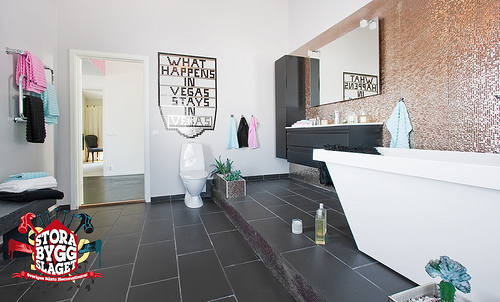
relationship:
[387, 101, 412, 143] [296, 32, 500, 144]
towel on wall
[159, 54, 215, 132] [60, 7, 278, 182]
poster on wall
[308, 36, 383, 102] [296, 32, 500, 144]
mirror on wall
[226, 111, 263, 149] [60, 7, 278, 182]
towels on wall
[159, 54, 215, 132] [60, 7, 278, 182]
sign on wall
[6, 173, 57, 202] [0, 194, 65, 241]
towels on bench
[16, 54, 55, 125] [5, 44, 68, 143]
towels hanging from rack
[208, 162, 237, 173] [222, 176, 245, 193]
small plant in pot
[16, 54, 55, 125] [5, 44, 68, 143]
towels on rack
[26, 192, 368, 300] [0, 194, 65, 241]
tile under bench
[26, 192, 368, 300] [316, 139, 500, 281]
floor under bathtub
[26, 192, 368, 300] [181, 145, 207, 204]
tile under toilet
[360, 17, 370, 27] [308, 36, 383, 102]
lights on mirror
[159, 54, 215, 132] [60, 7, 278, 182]
writing on wall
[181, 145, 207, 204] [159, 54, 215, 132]
toilet under poster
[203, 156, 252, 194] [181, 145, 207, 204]
plants next to toilet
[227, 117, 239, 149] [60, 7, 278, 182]
towel hanging on wall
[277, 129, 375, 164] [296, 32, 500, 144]
cabinet on wall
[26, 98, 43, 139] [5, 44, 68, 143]
towel on rack